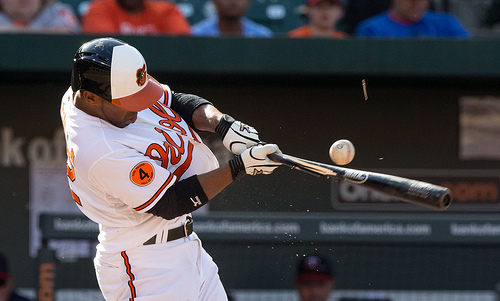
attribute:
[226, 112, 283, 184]
gloves — white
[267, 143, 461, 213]
bat — black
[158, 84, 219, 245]
sleeves — black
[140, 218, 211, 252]
belt — black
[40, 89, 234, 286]
uniform — white